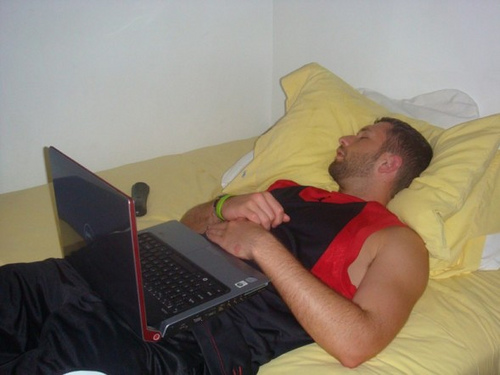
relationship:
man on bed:
[0, 118, 433, 374] [0, 135, 499, 374]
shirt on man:
[183, 180, 410, 374] [0, 118, 433, 374]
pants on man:
[0, 256, 146, 373] [0, 118, 433, 374]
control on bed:
[133, 184, 147, 216] [0, 135, 499, 374]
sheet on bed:
[0, 137, 499, 373] [0, 135, 499, 374]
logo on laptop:
[83, 224, 93, 240] [44, 145, 271, 343]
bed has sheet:
[0, 135, 499, 374] [0, 137, 499, 373]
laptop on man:
[44, 145, 271, 343] [0, 118, 433, 374]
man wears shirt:
[0, 118, 433, 374] [183, 180, 410, 374]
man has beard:
[0, 118, 433, 374] [329, 147, 384, 180]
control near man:
[133, 184, 147, 216] [0, 118, 433, 374]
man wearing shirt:
[0, 118, 433, 374] [183, 180, 410, 374]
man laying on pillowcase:
[0, 118, 433, 374] [222, 63, 499, 278]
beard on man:
[329, 147, 384, 180] [0, 118, 433, 374]